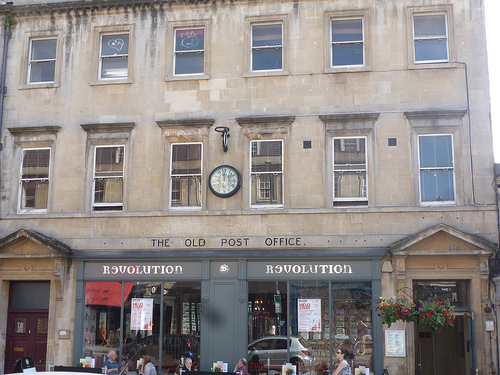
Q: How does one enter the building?
A: Through two entries.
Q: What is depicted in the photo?
A: A building.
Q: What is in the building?
A: Windows.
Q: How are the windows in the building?
A: Closed.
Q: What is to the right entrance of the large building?
A: A door.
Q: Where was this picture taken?
A: A Post Office.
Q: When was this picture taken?
A: Day time.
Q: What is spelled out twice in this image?
A: Revolution.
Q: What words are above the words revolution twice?
A: The Old Post Office.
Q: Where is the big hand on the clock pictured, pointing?
A: 12.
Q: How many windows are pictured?
A: 18.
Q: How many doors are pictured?
A: Two.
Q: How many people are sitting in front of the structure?
A: Five.